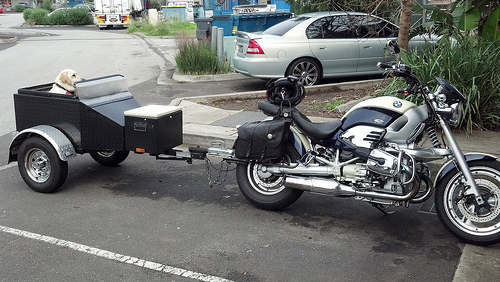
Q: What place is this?
A: It is a road.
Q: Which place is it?
A: It is a road.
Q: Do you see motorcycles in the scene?
A: Yes, there is a motorcycle.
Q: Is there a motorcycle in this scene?
A: Yes, there is a motorcycle.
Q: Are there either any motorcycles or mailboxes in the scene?
A: Yes, there is a motorcycle.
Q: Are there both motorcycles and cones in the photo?
A: No, there is a motorcycle but no cones.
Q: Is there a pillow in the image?
A: No, there are no pillows.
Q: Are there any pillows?
A: No, there are no pillows.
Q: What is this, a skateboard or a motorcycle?
A: This is a motorcycle.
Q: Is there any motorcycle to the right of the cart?
A: Yes, there is a motorcycle to the right of the cart.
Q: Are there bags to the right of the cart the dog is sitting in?
A: No, there is a motorcycle to the right of the cart.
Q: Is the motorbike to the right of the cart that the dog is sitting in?
A: Yes, the motorbike is to the right of the cart.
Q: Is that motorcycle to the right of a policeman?
A: No, the motorcycle is to the right of the cart.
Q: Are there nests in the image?
A: No, there are no nests.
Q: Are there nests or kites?
A: No, there are no nests or kites.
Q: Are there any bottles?
A: No, there are no bottles.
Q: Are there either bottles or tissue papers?
A: No, there are no bottles or tissue papers.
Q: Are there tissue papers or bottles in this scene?
A: No, there are no bottles or tissue papers.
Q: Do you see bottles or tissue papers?
A: No, there are no bottles or tissue papers.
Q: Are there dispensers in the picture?
A: No, there are no dispensers.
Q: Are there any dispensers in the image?
A: No, there are no dispensers.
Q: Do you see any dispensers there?
A: No, there are no dispensers.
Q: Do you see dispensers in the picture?
A: No, there are no dispensers.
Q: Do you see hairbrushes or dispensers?
A: No, there are no dispensers or hairbrushes.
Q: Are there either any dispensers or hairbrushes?
A: No, there are no dispensers or hairbrushes.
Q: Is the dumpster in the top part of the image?
A: Yes, the dumpster is in the top of the image.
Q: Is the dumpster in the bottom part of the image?
A: No, the dumpster is in the top of the image.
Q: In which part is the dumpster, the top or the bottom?
A: The dumpster is in the top of the image.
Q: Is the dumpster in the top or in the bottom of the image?
A: The dumpster is in the top of the image.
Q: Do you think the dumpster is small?
A: Yes, the dumpster is small.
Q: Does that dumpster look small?
A: Yes, the dumpster is small.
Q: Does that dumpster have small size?
A: Yes, the dumpster is small.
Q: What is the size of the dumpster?
A: The dumpster is small.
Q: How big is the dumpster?
A: The dumpster is small.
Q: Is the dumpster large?
A: No, the dumpster is small.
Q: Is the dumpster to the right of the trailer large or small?
A: The dumpster is small.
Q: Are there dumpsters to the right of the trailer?
A: Yes, there is a dumpster to the right of the trailer.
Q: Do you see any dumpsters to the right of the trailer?
A: Yes, there is a dumpster to the right of the trailer.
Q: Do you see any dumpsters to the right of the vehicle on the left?
A: Yes, there is a dumpster to the right of the trailer.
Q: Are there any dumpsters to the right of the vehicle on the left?
A: Yes, there is a dumpster to the right of the trailer.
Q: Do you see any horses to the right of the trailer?
A: No, there is a dumpster to the right of the trailer.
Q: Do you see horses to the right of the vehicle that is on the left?
A: No, there is a dumpster to the right of the trailer.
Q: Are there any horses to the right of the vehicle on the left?
A: No, there is a dumpster to the right of the trailer.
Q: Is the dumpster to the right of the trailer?
A: Yes, the dumpster is to the right of the trailer.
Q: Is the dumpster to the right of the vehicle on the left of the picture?
A: Yes, the dumpster is to the right of the trailer.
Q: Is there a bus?
A: No, there are no buses.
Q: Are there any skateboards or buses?
A: No, there are no buses or skateboards.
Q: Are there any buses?
A: No, there are no buses.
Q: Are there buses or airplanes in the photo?
A: No, there are no buses or airplanes.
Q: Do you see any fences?
A: No, there are no fences.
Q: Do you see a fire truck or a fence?
A: No, there are no fences or fire trucks.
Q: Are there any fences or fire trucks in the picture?
A: No, there are no fences or fire trucks.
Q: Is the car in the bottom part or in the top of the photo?
A: The car is in the top of the image.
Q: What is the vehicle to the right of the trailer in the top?
A: The vehicle is a car.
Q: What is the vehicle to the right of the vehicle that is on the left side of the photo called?
A: The vehicle is a car.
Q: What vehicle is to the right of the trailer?
A: The vehicle is a car.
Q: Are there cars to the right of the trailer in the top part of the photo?
A: Yes, there is a car to the right of the trailer.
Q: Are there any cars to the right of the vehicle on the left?
A: Yes, there is a car to the right of the trailer.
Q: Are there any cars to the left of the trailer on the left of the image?
A: No, the car is to the right of the trailer.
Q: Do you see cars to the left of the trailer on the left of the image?
A: No, the car is to the right of the trailer.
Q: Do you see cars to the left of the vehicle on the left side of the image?
A: No, the car is to the right of the trailer.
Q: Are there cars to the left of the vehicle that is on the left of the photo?
A: No, the car is to the right of the trailer.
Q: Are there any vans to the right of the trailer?
A: No, there is a car to the right of the trailer.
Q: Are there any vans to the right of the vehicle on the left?
A: No, there is a car to the right of the trailer.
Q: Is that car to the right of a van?
A: No, the car is to the right of the trailer.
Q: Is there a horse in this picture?
A: No, there are no horses.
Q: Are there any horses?
A: No, there are no horses.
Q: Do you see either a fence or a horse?
A: No, there are no horses or fences.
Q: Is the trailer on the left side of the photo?
A: Yes, the trailer is on the left of the image.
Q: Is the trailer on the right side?
A: No, the trailer is on the left of the image.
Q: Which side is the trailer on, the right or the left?
A: The trailer is on the left of the image.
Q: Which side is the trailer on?
A: The trailer is on the left of the image.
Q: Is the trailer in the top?
A: Yes, the trailer is in the top of the image.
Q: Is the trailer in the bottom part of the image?
A: No, the trailer is in the top of the image.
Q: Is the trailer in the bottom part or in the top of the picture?
A: The trailer is in the top of the image.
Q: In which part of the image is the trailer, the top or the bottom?
A: The trailer is in the top of the image.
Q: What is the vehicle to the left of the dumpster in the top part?
A: The vehicle is a trailer.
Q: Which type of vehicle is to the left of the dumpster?
A: The vehicle is a trailer.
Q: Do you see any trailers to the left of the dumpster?
A: Yes, there is a trailer to the left of the dumpster.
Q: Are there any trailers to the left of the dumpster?
A: Yes, there is a trailer to the left of the dumpster.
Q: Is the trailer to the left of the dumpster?
A: Yes, the trailer is to the left of the dumpster.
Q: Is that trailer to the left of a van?
A: No, the trailer is to the left of the dumpster.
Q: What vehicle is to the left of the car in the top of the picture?
A: The vehicle is a trailer.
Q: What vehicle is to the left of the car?
A: The vehicle is a trailer.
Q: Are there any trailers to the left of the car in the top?
A: Yes, there is a trailer to the left of the car.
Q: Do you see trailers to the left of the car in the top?
A: Yes, there is a trailer to the left of the car.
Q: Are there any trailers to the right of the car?
A: No, the trailer is to the left of the car.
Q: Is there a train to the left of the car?
A: No, there is a trailer to the left of the car.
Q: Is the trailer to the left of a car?
A: Yes, the trailer is to the left of a car.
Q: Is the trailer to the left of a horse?
A: No, the trailer is to the left of a car.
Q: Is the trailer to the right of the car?
A: No, the trailer is to the left of the car.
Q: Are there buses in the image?
A: No, there are no buses.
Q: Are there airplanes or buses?
A: No, there are no buses or airplanes.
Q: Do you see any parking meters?
A: No, there are no parking meters.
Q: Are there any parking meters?
A: No, there are no parking meters.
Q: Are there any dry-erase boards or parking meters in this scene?
A: No, there are no parking meters or dry-erase boards.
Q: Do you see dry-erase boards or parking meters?
A: No, there are no parking meters or dry-erase boards.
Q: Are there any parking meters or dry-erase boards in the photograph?
A: No, there are no parking meters or dry-erase boards.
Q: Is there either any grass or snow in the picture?
A: Yes, there is grass.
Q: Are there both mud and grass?
A: No, there is grass but no mud.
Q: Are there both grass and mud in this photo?
A: No, there is grass but no mud.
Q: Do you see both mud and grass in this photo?
A: No, there is grass but no mud.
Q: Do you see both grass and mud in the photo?
A: No, there is grass but no mud.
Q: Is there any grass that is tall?
A: Yes, there is grass that is tall.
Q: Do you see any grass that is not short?
A: Yes, there is tall grass.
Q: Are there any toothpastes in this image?
A: No, there are no toothpastes.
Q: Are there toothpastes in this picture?
A: No, there are no toothpastes.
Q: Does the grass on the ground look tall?
A: Yes, the grass is tall.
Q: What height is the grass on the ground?
A: The grass is tall.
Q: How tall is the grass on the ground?
A: The grass is tall.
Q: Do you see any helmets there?
A: Yes, there is a helmet.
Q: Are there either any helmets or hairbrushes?
A: Yes, there is a helmet.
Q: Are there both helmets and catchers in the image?
A: No, there is a helmet but no catchers.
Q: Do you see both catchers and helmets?
A: No, there is a helmet but no catchers.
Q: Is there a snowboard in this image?
A: No, there are no snowboards.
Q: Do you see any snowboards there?
A: No, there are no snowboards.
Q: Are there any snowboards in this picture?
A: No, there are no snowboards.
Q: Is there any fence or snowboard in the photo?
A: No, there are no snowboards or fences.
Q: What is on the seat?
A: The helmet is on the seat.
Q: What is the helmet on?
A: The helmet is on the seat.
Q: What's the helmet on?
A: The helmet is on the seat.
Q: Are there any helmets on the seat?
A: Yes, there is a helmet on the seat.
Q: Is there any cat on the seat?
A: No, there is a helmet on the seat.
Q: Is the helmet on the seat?
A: Yes, the helmet is on the seat.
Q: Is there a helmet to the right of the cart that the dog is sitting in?
A: Yes, there is a helmet to the right of the cart.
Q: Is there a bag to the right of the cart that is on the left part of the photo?
A: No, there is a helmet to the right of the cart.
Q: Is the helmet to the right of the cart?
A: Yes, the helmet is to the right of the cart.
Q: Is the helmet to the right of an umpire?
A: No, the helmet is to the right of the cart.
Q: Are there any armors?
A: No, there are no armors.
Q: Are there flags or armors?
A: No, there are no armors or flags.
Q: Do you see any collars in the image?
A: Yes, there is a collar.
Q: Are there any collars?
A: Yes, there is a collar.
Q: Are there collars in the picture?
A: Yes, there is a collar.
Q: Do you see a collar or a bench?
A: Yes, there is a collar.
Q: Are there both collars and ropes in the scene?
A: No, there is a collar but no ropes.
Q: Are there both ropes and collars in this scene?
A: No, there is a collar but no ropes.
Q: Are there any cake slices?
A: No, there are no cake slices.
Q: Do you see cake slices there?
A: No, there are no cake slices.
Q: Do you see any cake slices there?
A: No, there are no cake slices.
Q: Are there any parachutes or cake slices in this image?
A: No, there are no cake slices or parachutes.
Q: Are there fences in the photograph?
A: No, there are no fences.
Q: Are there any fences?
A: No, there are no fences.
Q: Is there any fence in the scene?
A: No, there are no fences.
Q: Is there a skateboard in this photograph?
A: No, there are no skateboards.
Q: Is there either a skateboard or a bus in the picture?
A: No, there are no skateboards or buses.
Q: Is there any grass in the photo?
A: Yes, there is grass.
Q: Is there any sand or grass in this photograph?
A: Yes, there is grass.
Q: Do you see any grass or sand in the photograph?
A: Yes, there is grass.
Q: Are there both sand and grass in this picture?
A: No, there is grass but no sand.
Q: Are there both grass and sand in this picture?
A: No, there is grass but no sand.